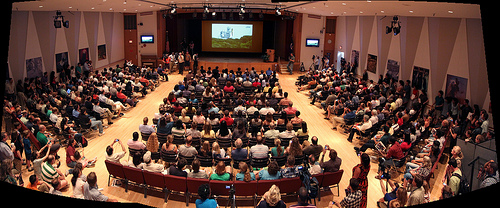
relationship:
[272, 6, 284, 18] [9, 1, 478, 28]
light fixture attached to ceiling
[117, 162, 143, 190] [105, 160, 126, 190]
seats sitting in seats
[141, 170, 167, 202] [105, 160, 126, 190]
seats sitting in seats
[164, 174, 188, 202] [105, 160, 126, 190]
seats sitting in seats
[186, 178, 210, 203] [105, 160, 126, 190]
seats sitting in seats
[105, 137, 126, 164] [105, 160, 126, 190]
people sitting in seats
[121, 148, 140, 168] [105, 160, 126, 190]
people sitting in seats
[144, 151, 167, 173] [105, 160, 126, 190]
people sitting in seats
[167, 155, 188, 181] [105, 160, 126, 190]
people sitting in seats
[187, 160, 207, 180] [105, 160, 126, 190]
people sitting in seats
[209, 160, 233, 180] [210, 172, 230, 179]
woman wearing a shirt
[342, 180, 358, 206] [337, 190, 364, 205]
man wearing a shirt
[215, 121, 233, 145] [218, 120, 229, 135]
woman with hair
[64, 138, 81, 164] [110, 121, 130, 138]
woman sitting on floor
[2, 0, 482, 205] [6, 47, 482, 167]
large auditorium of people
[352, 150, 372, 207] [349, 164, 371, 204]
woman wearing dress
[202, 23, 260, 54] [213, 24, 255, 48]
film playing on a screen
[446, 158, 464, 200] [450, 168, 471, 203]
man wearing a black backpack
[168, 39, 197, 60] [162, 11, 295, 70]
people standing on a stage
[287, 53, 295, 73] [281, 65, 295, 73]
person standing on stairs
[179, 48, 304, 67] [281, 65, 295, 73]
stage has stairs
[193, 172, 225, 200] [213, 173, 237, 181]
woman in a shirt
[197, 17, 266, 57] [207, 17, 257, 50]
screen has image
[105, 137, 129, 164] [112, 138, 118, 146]
people using camera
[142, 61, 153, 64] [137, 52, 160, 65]
bench in front of piano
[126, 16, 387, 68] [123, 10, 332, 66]
screens are on wall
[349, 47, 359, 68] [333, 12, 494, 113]
painting on wall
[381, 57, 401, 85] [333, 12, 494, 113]
painting on wall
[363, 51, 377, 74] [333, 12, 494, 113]
painting on wall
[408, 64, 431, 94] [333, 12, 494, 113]
painting on wall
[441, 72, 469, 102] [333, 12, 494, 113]
painting on wall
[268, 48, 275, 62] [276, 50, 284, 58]
podium next to plant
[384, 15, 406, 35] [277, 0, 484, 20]
light hanging from ceiling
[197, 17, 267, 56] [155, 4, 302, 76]
screen on stage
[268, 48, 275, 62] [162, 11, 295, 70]
podium at stage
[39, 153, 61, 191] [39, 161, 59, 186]
man in shirt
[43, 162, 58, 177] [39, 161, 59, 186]
stripe on shirt